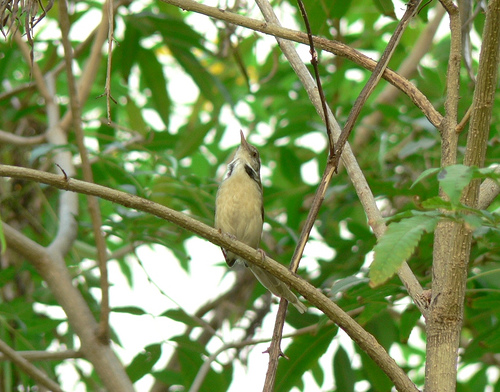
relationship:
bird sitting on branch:
[213, 129, 309, 317] [10, 160, 430, 370]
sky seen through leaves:
[99, 1, 324, 390] [360, 160, 499, 277]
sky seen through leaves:
[99, 1, 324, 390] [103, 6, 325, 240]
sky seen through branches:
[99, 1, 324, 390] [4, 2, 169, 389]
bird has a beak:
[213, 129, 309, 317] [233, 124, 250, 152]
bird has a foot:
[180, 126, 342, 276] [237, 251, 315, 285]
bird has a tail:
[213, 129, 309, 317] [245, 247, 316, 324]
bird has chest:
[213, 129, 309, 317] [216, 179, 260, 238]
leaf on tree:
[365, 209, 427, 289] [2, 2, 497, 389]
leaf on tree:
[269, 324, 338, 389] [2, 2, 497, 389]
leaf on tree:
[438, 163, 473, 211] [2, 2, 497, 389]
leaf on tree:
[138, 15, 206, 47] [2, 2, 497, 389]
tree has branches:
[24, 40, 489, 340] [228, 20, 420, 204]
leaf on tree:
[135, 45, 175, 130] [2, 2, 497, 389]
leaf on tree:
[225, 33, 266, 105] [273, 9, 498, 321]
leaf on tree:
[271, 111, 300, 166] [2, 2, 497, 389]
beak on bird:
[239, 130, 246, 145] [215, 127, 265, 266]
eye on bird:
[244, 148, 266, 158] [215, 127, 265, 266]